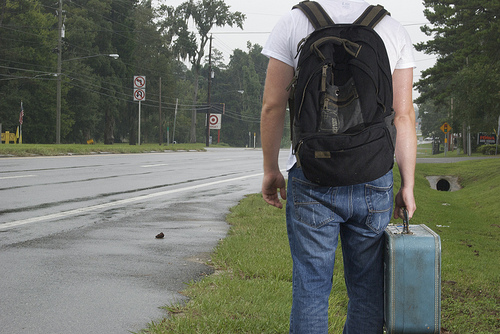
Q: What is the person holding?
A: A suitcase.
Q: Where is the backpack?
A: On the person's back.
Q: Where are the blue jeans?
A: On the person's legs.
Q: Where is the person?
A: On the grass.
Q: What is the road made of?
A: Asphalt.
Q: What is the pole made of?
A: Metal.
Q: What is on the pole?
A: Signs.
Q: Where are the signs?
A: On the pole.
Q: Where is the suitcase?
A: In the hand.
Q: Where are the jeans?
A: On the man.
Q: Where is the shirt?
A: On the man.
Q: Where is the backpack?
A: On the man.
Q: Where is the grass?
A: On the ground.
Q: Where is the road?
A: On the ground.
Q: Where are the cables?
A: In the air.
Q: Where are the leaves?
A: In the trees.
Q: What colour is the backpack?
A: Black.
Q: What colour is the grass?
A: Green.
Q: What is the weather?
A: Rainy.